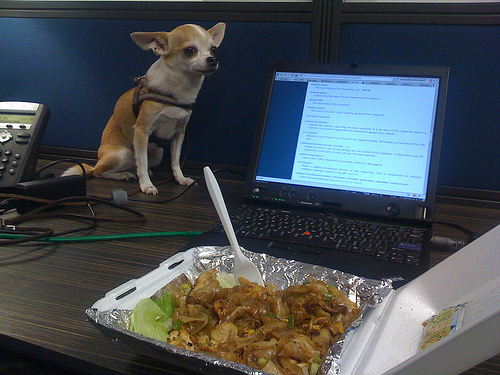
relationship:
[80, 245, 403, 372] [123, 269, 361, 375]
foil on foil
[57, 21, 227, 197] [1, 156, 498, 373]
chihuahua on desk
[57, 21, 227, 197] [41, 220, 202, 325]
chihuahua on desk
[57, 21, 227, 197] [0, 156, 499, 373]
chihuahua on table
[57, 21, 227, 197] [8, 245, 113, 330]
chihuahua on wooden table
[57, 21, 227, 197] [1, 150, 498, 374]
chihuahua on wooden table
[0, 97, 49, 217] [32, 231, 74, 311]
electronic device on table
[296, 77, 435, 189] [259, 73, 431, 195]
image on screen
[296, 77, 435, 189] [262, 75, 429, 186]
image on screen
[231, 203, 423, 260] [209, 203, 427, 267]
buttons on buttons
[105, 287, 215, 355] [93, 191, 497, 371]
lettuce in container